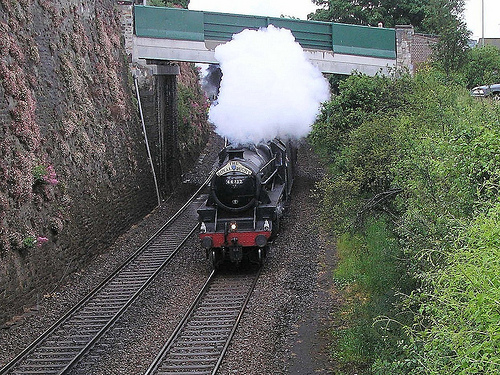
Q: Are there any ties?
A: Yes, there is a tie.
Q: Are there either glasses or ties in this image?
A: Yes, there is a tie.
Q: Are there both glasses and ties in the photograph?
A: No, there is a tie but no glasses.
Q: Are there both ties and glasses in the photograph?
A: No, there is a tie but no glasses.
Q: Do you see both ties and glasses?
A: No, there is a tie but no glasses.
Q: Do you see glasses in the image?
A: No, there are no glasses.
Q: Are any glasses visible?
A: No, there are no glasses.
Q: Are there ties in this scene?
A: Yes, there is a tie.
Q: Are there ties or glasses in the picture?
A: Yes, there is a tie.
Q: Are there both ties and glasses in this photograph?
A: No, there is a tie but no glasses.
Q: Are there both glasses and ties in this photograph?
A: No, there is a tie but no glasses.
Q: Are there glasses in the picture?
A: No, there are no glasses.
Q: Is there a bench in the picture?
A: No, there are no benches.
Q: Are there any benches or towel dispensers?
A: No, there are no benches or towel dispensers.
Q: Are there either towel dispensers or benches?
A: No, there are no benches or towel dispensers.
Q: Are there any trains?
A: Yes, there is a train.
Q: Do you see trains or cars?
A: Yes, there is a train.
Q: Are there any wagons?
A: No, there are no wagons.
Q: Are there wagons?
A: No, there are no wagons.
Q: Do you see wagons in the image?
A: No, there are no wagons.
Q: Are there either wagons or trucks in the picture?
A: No, there are no wagons or trucks.